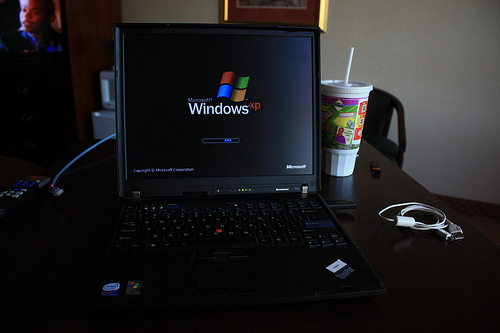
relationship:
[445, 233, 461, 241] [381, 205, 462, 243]
plugs on cord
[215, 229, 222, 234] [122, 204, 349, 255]
button on keyboard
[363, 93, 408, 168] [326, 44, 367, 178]
chair behind cup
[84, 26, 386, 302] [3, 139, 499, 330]
laptop on table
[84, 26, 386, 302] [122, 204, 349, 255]
laptop has keyboard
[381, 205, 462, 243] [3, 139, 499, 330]
cord on table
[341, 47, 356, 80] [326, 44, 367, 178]
straw in cup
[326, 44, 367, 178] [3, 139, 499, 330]
cup on table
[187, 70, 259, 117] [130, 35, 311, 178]
logo on screen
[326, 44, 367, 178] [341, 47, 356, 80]
cup has straw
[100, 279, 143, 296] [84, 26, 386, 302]
stickers on laptop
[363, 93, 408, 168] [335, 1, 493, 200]
chair near wall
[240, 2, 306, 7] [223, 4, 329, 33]
picture has frame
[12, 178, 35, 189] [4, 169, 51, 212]
buttons on remote control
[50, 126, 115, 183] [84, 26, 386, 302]
wire behind laptop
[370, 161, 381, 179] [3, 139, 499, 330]
thumbdrive on table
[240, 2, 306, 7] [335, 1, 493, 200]
picture on wall